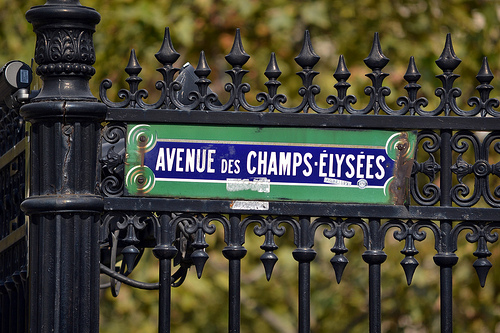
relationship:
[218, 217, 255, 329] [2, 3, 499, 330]
banister of fence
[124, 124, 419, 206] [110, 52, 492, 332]
green sign on fence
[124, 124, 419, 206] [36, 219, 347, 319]
green sign on fence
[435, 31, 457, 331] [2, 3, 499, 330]
spoke on fence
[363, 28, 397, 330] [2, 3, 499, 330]
spoke on fence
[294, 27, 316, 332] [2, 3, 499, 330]
spoke on fence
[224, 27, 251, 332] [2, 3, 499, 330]
spoke on fence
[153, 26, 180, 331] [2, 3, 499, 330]
spoke on fence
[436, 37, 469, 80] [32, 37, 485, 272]
spike on top of fence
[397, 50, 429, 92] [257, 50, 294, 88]
spike on top of spike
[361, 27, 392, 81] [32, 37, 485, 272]
spike on top of fence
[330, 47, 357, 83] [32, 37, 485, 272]
spike on top of fence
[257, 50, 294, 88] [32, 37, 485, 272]
spike on top of fence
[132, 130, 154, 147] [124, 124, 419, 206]
bolt on green sign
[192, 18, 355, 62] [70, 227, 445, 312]
foliage behind fence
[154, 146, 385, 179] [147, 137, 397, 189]
letters on sign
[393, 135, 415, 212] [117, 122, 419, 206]
rust on sign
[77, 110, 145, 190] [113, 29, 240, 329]
camera inside fence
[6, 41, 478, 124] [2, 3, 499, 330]
decoration on fence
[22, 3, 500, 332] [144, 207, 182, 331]
fence has banister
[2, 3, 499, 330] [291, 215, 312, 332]
fence has banister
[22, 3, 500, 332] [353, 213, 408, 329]
fence has banister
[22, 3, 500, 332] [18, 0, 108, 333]
fence has fence post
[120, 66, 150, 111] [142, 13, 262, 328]
part of a fence